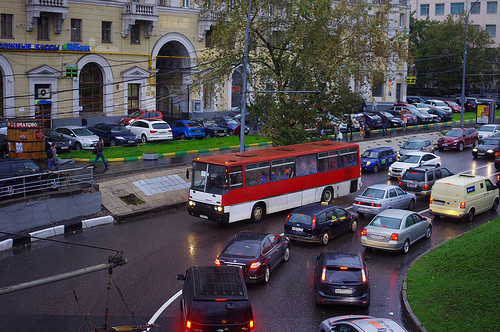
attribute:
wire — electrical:
[0, 32, 242, 88]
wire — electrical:
[3, 47, 245, 108]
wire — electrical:
[5, 54, 245, 118]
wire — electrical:
[28, 59, 244, 123]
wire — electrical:
[254, 32, 463, 65]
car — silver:
[360, 205, 433, 253]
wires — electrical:
[1, 40, 491, 124]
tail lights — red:
[358, 226, 400, 243]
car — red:
[120, 103, 165, 128]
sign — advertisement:
[473, 102, 490, 128]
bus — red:
[178, 136, 370, 230]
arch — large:
[152, 33, 199, 121]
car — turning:
[177, 265, 252, 330]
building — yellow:
[2, 0, 419, 125]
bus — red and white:
[187, 139, 362, 224]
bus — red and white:
[194, 130, 375, 216]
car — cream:
[419, 172, 498, 225]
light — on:
[359, 265, 366, 282]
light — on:
[320, 263, 327, 281]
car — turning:
[305, 242, 379, 324]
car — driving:
[214, 230, 290, 284]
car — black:
[299, 252, 366, 320]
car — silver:
[314, 304, 409, 330]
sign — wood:
[7, 116, 52, 160]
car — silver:
[349, 175, 417, 220]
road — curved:
[25, 124, 479, 316]